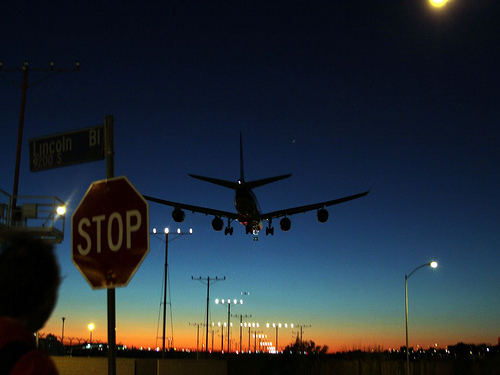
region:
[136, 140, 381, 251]
Plane taking off in the sky.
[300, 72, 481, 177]
Night time approaching.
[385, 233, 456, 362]
Silver light pole right of plane.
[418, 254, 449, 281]
Light on light pole turned on.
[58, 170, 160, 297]
Stop sign on pole.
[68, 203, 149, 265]
White lettering on stop sign.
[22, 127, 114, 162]
Street sign says Lincoln BI.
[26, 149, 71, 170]
Numbering under street sign.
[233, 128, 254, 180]
Tail end of the plane.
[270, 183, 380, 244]
Wing and propellers of plane.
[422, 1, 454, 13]
yellow light in black and blue night in the sky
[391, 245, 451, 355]
tall street light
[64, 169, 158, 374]
red and white stop sign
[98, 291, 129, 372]
metal pole with street sign on it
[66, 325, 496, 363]
silhouette of trees and shrubbery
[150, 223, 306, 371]
row of white street lights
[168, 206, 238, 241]
wheels on bottom of airplane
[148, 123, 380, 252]
airplane flying low in the sky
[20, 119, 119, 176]
green street sign on pole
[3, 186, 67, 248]
elevated metal platform with metal railing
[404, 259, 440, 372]
light on lamp post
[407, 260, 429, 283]
metal arm on lap post supporting a light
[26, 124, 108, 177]
rectangular sign above red stop sign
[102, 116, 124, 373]
stop sign attached to metal pole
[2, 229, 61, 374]
person to the left of stop sign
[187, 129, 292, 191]
tail of plane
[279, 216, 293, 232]
engines hanging under wings of plane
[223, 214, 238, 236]
landing gear under plane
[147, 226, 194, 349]
utility pole next to utility pole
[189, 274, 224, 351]
utility pole is off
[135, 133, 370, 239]
Airplane with wheels down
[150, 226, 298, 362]
Lights on a runway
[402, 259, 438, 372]
Street lamp near a runway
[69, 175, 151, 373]
Stop sign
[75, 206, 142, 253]
The word stop in white letters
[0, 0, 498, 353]
A clear sky at sunset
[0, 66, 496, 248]
Dark blue sky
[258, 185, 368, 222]
Right wing of an airplane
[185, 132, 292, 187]
Tail of an airplane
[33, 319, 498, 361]
Streetlights in the distance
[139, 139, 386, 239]
a large passenger jet flying through the sky.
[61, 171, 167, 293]
a red stop sign on a pole.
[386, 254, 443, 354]
a street light under a plane.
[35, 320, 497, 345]
an orange sky at sunset.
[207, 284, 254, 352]
a very tall light.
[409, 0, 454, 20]
the moon sitting in the sky.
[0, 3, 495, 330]
a beautiful blue sky at sunset.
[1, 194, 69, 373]
a large tank near a stop sign.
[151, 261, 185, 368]
a very tall power line.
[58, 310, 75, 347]
a very tall light.